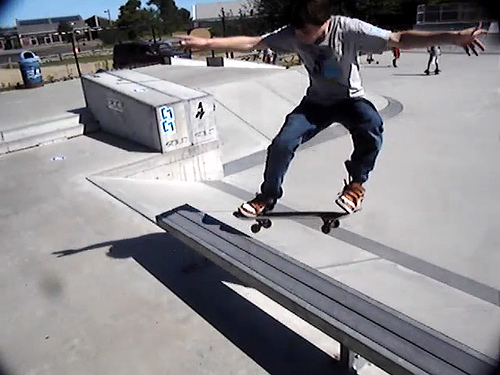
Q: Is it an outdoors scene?
A: Yes, it is outdoors.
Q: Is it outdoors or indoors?
A: It is outdoors.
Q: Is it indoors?
A: No, it is outdoors.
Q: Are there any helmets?
A: No, there are no helmets.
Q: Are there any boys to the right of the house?
A: Yes, there is a boy to the right of the house.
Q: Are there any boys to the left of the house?
A: No, the boy is to the right of the house.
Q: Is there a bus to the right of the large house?
A: No, there is a boy to the right of the house.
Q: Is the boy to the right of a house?
A: Yes, the boy is to the right of a house.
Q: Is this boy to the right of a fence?
A: No, the boy is to the right of a house.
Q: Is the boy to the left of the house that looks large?
A: No, the boy is to the right of the house.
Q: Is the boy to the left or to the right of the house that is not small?
A: The boy is to the right of the house.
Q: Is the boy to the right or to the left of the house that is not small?
A: The boy is to the right of the house.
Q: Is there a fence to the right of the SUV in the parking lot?
A: No, there is a boy to the right of the SUV.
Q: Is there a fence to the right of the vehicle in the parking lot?
A: No, there is a boy to the right of the SUV.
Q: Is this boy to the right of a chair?
A: No, the boy is to the right of the SUV.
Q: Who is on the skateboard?
A: The boy is on the skateboard.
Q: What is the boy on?
A: The boy is on the skateboard.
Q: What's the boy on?
A: The boy is on the skateboard.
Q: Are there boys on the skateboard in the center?
A: Yes, there is a boy on the skateboard.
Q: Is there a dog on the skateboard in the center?
A: No, there is a boy on the skateboard.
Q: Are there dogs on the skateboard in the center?
A: No, there is a boy on the skateboard.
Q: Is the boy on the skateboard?
A: Yes, the boy is on the skateboard.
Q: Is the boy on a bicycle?
A: No, the boy is on the skateboard.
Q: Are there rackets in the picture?
A: No, there are no rackets.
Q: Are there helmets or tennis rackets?
A: No, there are no tennis rackets or helmets.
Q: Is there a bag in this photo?
A: No, there are no bags.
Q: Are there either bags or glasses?
A: No, there are no bags or glasses.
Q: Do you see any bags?
A: No, there are no bags.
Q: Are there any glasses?
A: No, there are no glasses.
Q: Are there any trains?
A: No, there are no trains.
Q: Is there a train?
A: No, there are no trains.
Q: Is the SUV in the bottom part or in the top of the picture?
A: The SUV is in the top of the image.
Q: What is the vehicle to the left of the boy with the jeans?
A: The vehicle is a SUV.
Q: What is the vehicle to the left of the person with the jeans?
A: The vehicle is a SUV.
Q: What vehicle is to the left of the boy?
A: The vehicle is a SUV.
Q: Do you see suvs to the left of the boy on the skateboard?
A: Yes, there is a SUV to the left of the boy.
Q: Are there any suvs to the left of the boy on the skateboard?
A: Yes, there is a SUV to the left of the boy.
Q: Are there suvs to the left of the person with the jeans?
A: Yes, there is a SUV to the left of the boy.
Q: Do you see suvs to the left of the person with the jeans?
A: Yes, there is a SUV to the left of the boy.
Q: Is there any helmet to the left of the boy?
A: No, there is a SUV to the left of the boy.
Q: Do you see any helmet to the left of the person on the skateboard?
A: No, there is a SUV to the left of the boy.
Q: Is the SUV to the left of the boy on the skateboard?
A: Yes, the SUV is to the left of the boy.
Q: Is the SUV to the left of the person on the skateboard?
A: Yes, the SUV is to the left of the boy.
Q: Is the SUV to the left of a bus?
A: No, the SUV is to the left of the boy.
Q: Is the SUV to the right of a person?
A: No, the SUV is to the left of a person.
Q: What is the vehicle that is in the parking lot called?
A: The vehicle is a SUV.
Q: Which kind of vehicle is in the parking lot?
A: The vehicle is a SUV.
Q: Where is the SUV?
A: The SUV is in the parking lot.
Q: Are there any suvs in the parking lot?
A: Yes, there is a SUV in the parking lot.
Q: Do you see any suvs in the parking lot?
A: Yes, there is a SUV in the parking lot.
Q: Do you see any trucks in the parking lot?
A: No, there is a SUV in the parking lot.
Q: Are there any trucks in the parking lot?
A: No, there is a SUV in the parking lot.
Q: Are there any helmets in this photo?
A: No, there are no helmets.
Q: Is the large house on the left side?
A: Yes, the house is on the left of the image.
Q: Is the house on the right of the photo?
A: No, the house is on the left of the image.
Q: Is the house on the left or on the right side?
A: The house is on the left of the image.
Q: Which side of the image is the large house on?
A: The house is on the left of the image.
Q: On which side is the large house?
A: The house is on the left of the image.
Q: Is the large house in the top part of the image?
A: Yes, the house is in the top of the image.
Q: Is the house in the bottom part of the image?
A: No, the house is in the top of the image.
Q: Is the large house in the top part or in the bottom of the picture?
A: The house is in the top of the image.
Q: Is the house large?
A: Yes, the house is large.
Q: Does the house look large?
A: Yes, the house is large.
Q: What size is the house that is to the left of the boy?
A: The house is large.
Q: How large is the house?
A: The house is large.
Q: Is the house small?
A: No, the house is large.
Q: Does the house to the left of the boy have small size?
A: No, the house is large.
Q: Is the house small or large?
A: The house is large.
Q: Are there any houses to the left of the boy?
A: Yes, there is a house to the left of the boy.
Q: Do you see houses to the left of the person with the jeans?
A: Yes, there is a house to the left of the boy.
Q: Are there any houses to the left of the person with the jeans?
A: Yes, there is a house to the left of the boy.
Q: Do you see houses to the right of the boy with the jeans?
A: No, the house is to the left of the boy.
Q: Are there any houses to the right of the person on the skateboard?
A: No, the house is to the left of the boy.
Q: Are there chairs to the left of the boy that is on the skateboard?
A: No, there is a house to the left of the boy.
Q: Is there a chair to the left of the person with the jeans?
A: No, there is a house to the left of the boy.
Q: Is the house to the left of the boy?
A: Yes, the house is to the left of the boy.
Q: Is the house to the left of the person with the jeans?
A: Yes, the house is to the left of the boy.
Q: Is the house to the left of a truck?
A: No, the house is to the left of the boy.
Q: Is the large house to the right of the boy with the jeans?
A: No, the house is to the left of the boy.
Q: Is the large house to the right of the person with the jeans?
A: No, the house is to the left of the boy.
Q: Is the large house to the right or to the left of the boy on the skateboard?
A: The house is to the left of the boy.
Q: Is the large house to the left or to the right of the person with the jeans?
A: The house is to the left of the boy.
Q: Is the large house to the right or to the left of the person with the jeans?
A: The house is to the left of the boy.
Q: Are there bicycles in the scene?
A: No, there are no bicycles.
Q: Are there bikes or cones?
A: No, there are no bikes or cones.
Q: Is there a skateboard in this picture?
A: Yes, there is a skateboard.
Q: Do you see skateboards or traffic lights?
A: Yes, there is a skateboard.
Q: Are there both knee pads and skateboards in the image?
A: No, there is a skateboard but no knee pads.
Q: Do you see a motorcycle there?
A: No, there are no motorcycles.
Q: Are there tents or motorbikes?
A: No, there are no motorbikes or tents.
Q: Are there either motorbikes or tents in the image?
A: No, there are no motorbikes or tents.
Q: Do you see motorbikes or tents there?
A: No, there are no motorbikes or tents.